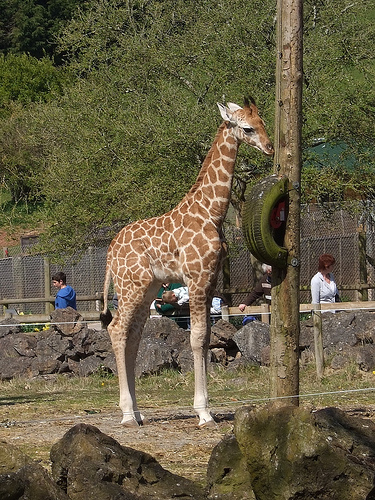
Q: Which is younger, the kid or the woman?
A: The kid is younger than the woman.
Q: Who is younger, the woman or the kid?
A: The kid is younger than the woman.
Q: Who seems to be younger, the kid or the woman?
A: The kid is younger than the woman.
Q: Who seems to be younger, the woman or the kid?
A: The kid is younger than the woman.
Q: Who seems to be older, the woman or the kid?
A: The woman is older than the kid.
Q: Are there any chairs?
A: No, there are no chairs.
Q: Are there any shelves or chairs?
A: No, there are no chairs or shelves.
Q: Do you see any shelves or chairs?
A: No, there are no chairs or shelves.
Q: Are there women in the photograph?
A: Yes, there is a woman.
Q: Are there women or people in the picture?
A: Yes, there is a woman.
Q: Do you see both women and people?
A: Yes, there are both a woman and a person.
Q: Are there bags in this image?
A: No, there are no bags.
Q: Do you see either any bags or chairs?
A: No, there are no bags or chairs.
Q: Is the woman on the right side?
A: Yes, the woman is on the right of the image.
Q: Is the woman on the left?
A: No, the woman is on the right of the image.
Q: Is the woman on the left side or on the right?
A: The woman is on the right of the image.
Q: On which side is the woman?
A: The woman is on the right of the image.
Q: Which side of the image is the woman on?
A: The woman is on the right of the image.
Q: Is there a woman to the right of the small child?
A: Yes, there is a woman to the right of the kid.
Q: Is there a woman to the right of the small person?
A: Yes, there is a woman to the right of the kid.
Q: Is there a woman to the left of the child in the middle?
A: No, the woman is to the right of the child.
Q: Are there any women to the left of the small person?
A: No, the woman is to the right of the child.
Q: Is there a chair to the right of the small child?
A: No, there is a woman to the right of the child.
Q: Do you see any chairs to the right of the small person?
A: No, there is a woman to the right of the child.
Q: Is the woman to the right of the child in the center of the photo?
A: Yes, the woman is to the right of the kid.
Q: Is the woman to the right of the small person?
A: Yes, the woman is to the right of the kid.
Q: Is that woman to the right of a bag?
A: No, the woman is to the right of the kid.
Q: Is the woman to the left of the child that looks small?
A: No, the woman is to the right of the kid.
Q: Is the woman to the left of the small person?
A: No, the woman is to the right of the kid.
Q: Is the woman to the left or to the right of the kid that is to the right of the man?
A: The woman is to the right of the child.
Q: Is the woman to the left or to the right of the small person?
A: The woman is to the right of the child.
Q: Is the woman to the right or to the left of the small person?
A: The woman is to the right of the child.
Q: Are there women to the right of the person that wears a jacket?
A: Yes, there is a woman to the right of the person.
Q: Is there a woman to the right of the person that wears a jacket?
A: Yes, there is a woman to the right of the person.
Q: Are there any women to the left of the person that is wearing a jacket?
A: No, the woman is to the right of the person.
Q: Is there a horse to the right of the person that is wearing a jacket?
A: No, there is a woman to the right of the person.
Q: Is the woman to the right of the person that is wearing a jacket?
A: Yes, the woman is to the right of the person.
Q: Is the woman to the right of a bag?
A: No, the woman is to the right of the person.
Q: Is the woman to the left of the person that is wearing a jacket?
A: No, the woman is to the right of the person.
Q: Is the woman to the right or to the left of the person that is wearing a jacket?
A: The woman is to the right of the person.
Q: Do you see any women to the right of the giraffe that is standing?
A: Yes, there is a woman to the right of the giraffe.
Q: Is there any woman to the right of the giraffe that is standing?
A: Yes, there is a woman to the right of the giraffe.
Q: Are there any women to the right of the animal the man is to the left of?
A: Yes, there is a woman to the right of the giraffe.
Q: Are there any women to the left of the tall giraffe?
A: No, the woman is to the right of the giraffe.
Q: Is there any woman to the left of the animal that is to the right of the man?
A: No, the woman is to the right of the giraffe.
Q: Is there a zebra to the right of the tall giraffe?
A: No, there is a woman to the right of the giraffe.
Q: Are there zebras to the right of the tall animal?
A: No, there is a woman to the right of the giraffe.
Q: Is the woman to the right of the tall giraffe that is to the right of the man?
A: Yes, the woman is to the right of the giraffe.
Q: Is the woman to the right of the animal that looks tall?
A: Yes, the woman is to the right of the giraffe.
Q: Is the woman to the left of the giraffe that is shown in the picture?
A: No, the woman is to the right of the giraffe.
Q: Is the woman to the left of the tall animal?
A: No, the woman is to the right of the giraffe.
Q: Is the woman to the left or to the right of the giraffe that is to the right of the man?
A: The woman is to the right of the giraffe.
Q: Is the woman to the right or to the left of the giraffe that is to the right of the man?
A: The woman is to the right of the giraffe.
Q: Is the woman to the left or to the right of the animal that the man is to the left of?
A: The woman is to the right of the giraffe.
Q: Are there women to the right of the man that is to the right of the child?
A: Yes, there is a woman to the right of the man.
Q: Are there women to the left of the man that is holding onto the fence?
A: No, the woman is to the right of the man.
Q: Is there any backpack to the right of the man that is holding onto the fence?
A: No, there is a woman to the right of the man.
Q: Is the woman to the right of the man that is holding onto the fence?
A: Yes, the woman is to the right of the man.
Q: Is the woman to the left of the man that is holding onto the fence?
A: No, the woman is to the right of the man.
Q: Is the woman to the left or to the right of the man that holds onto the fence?
A: The woman is to the right of the man.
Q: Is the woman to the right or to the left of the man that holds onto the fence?
A: The woman is to the right of the man.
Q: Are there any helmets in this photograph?
A: No, there are no helmets.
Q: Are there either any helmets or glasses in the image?
A: No, there are no helmets or glasses.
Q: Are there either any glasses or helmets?
A: No, there are no helmets or glasses.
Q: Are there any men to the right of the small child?
A: Yes, there is a man to the right of the child.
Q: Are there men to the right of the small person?
A: Yes, there is a man to the right of the child.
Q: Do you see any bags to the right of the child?
A: No, there is a man to the right of the child.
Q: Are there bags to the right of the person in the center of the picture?
A: No, there is a man to the right of the child.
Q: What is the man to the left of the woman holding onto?
A: The man is holding onto the fence.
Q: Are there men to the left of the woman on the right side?
A: Yes, there is a man to the left of the woman.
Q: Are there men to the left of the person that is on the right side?
A: Yes, there is a man to the left of the woman.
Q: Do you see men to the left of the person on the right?
A: Yes, there is a man to the left of the woman.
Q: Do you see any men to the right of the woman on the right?
A: No, the man is to the left of the woman.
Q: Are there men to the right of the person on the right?
A: No, the man is to the left of the woman.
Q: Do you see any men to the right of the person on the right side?
A: No, the man is to the left of the woman.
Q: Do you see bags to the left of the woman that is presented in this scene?
A: No, there is a man to the left of the woman.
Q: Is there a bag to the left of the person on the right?
A: No, there is a man to the left of the woman.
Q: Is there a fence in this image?
A: Yes, there is a fence.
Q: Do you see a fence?
A: Yes, there is a fence.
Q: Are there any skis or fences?
A: Yes, there is a fence.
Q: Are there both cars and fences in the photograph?
A: No, there is a fence but no cars.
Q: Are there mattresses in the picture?
A: No, there are no mattresses.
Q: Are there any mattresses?
A: No, there are no mattresses.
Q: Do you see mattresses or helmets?
A: No, there are no mattresses or helmets.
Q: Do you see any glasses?
A: No, there are no glasses.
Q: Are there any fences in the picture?
A: Yes, there is a fence.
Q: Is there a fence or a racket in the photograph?
A: Yes, there is a fence.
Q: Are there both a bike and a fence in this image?
A: No, there is a fence but no bikes.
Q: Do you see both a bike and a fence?
A: No, there is a fence but no bikes.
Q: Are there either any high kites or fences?
A: Yes, there is a high fence.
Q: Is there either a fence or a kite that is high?
A: Yes, the fence is high.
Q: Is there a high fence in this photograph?
A: Yes, there is a high fence.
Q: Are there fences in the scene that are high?
A: Yes, there is a high fence.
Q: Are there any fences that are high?
A: Yes, there is a fence that is high.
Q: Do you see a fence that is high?
A: Yes, there is a fence that is high.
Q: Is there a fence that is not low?
A: Yes, there is a high fence.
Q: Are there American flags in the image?
A: No, there are no American flags.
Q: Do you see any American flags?
A: No, there are no American flags.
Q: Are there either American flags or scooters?
A: No, there are no American flags or scooters.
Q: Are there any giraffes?
A: Yes, there is a giraffe.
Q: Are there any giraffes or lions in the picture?
A: Yes, there is a giraffe.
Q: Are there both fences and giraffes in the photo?
A: Yes, there are both a giraffe and a fence.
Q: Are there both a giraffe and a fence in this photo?
A: Yes, there are both a giraffe and a fence.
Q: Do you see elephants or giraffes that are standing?
A: Yes, the giraffe is standing.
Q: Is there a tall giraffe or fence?
A: Yes, there is a tall giraffe.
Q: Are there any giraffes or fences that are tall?
A: Yes, the giraffe is tall.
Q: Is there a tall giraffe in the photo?
A: Yes, there is a tall giraffe.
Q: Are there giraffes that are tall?
A: Yes, there is a giraffe that is tall.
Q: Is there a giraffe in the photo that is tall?
A: Yes, there is a giraffe that is tall.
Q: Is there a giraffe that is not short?
A: Yes, there is a tall giraffe.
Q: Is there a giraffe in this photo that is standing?
A: Yes, there is a giraffe that is standing.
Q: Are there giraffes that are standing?
A: Yes, there is a giraffe that is standing.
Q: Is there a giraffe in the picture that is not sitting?
A: Yes, there is a giraffe that is standing.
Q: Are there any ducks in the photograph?
A: No, there are no ducks.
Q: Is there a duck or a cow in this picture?
A: No, there are no ducks or cows.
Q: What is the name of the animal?
A: The animal is a giraffe.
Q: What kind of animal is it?
A: The animal is a giraffe.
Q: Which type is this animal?
A: This is a giraffe.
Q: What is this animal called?
A: This is a giraffe.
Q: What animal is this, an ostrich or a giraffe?
A: This is a giraffe.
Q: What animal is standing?
A: The animal is a giraffe.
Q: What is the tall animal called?
A: The animal is a giraffe.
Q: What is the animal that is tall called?
A: The animal is a giraffe.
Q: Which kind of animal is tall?
A: The animal is a giraffe.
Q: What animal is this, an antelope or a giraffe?
A: This is a giraffe.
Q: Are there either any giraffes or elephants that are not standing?
A: No, there is a giraffe but it is standing.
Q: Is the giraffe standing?
A: Yes, the giraffe is standing.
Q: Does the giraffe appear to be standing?
A: Yes, the giraffe is standing.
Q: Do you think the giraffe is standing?
A: Yes, the giraffe is standing.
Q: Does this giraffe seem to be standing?
A: Yes, the giraffe is standing.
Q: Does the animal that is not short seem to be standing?
A: Yes, the giraffe is standing.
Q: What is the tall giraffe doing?
A: The giraffe is standing.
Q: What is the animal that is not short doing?
A: The giraffe is standing.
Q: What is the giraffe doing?
A: The giraffe is standing.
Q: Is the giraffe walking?
A: No, the giraffe is standing.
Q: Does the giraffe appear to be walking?
A: No, the giraffe is standing.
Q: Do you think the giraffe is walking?
A: No, the giraffe is standing.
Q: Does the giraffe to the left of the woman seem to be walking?
A: No, the giraffe is standing.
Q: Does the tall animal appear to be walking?
A: No, the giraffe is standing.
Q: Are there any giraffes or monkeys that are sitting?
A: No, there is a giraffe but it is standing.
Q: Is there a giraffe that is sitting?
A: No, there is a giraffe but it is standing.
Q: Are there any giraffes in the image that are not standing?
A: No, there is a giraffe but it is standing.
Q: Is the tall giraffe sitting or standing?
A: The giraffe is standing.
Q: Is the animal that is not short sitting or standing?
A: The giraffe is standing.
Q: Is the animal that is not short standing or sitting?
A: The giraffe is standing.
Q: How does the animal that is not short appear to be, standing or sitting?
A: The giraffe is standing.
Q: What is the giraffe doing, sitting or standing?
A: The giraffe is standing.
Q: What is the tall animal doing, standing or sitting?
A: The giraffe is standing.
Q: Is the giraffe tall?
A: Yes, the giraffe is tall.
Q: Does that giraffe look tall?
A: Yes, the giraffe is tall.